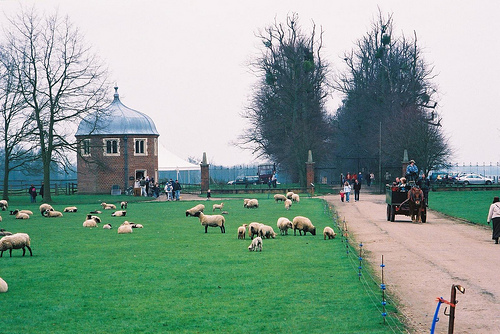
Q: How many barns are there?
A: One.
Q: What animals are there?
A: Sheep.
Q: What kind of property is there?
A: Farm.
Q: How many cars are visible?
A: One.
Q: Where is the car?
A: Parked near tree.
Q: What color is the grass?
A: Green.